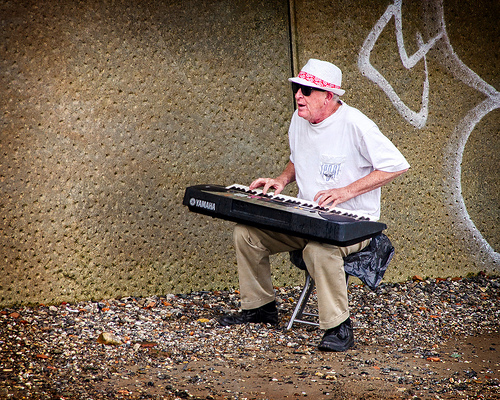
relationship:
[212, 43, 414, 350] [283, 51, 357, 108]
man wearing hat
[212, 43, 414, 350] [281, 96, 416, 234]
man wearing shirt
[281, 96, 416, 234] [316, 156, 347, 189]
shirt has design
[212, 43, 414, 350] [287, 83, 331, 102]
man wearing sunglasses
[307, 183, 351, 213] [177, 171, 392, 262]
left hand on keyboard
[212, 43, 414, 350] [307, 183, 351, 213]
man has left hand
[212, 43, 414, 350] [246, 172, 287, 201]
man has right hand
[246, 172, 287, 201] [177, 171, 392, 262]
right hand on keyboard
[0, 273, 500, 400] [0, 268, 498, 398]
ground on ground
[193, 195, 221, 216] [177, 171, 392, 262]
lettering on keyboard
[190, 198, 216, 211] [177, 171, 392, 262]
lettering on keyboard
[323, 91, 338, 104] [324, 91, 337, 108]
hearing aid in ear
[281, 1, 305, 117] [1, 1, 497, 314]
dent in wall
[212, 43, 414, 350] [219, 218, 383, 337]
man wearing pants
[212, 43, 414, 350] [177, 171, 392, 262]
man has keyboard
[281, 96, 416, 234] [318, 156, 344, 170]
shirt has pocket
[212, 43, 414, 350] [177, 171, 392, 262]
man playing keyboard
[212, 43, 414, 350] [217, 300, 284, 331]
man has foot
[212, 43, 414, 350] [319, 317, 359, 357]
man has foot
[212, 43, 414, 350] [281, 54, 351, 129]
man has head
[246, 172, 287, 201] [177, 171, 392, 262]
right hand playing keyboard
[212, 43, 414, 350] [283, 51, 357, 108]
man has hat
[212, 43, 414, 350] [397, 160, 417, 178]
man has elbow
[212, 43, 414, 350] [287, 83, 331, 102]
man has sunglasses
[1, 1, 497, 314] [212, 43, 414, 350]
wall behind man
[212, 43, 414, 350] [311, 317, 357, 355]
man wearing shoe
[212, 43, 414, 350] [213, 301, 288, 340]
man wearing shoe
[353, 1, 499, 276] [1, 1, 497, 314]
tag on wall